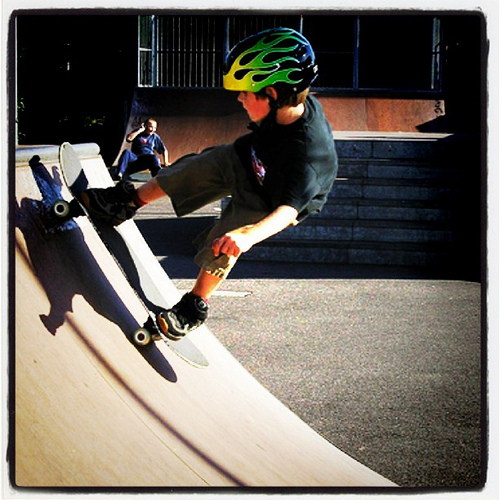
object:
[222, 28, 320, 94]
flame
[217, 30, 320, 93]
helmet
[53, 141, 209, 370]
skateboard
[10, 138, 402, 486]
ramp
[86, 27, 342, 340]
child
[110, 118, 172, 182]
skater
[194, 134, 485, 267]
ramp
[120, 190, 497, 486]
pavement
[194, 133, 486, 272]
steps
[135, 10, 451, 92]
fence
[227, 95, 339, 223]
shirt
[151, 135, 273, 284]
shorts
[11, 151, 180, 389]
shadow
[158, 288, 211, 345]
shoes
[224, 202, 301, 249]
arm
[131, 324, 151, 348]
wheels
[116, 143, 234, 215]
leg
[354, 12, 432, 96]
window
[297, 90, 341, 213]
back